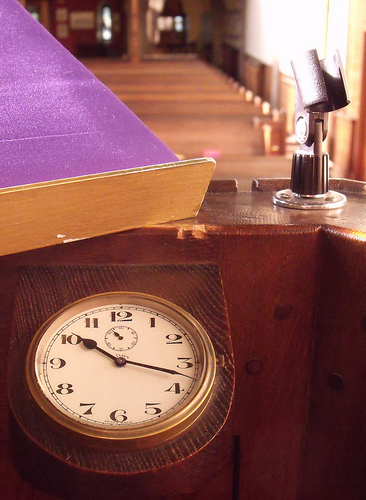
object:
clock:
[6, 256, 240, 479]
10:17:
[61, 314, 203, 428]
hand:
[73, 331, 114, 367]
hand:
[125, 358, 188, 381]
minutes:
[33, 294, 204, 432]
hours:
[30, 300, 213, 432]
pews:
[72, 46, 295, 157]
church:
[1, 2, 364, 500]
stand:
[2, 1, 217, 261]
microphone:
[289, 41, 355, 119]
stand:
[271, 110, 354, 214]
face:
[31, 289, 219, 430]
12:
[106, 305, 137, 326]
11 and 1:
[82, 309, 160, 332]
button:
[1, 220, 366, 499]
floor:
[63, 46, 347, 189]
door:
[153, 1, 193, 50]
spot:
[51, 232, 68, 240]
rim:
[24, 289, 219, 444]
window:
[98, 6, 118, 47]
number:
[140, 399, 166, 418]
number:
[107, 405, 133, 424]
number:
[78, 399, 99, 418]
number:
[54, 381, 77, 397]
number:
[164, 379, 184, 400]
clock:
[102, 325, 138, 353]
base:
[271, 189, 351, 210]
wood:
[2, 176, 365, 256]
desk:
[1, 178, 366, 500]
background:
[0, 1, 365, 192]